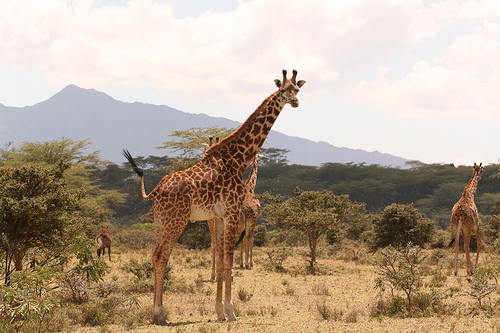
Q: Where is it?
A: This is at the plain.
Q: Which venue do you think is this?
A: This is a plain.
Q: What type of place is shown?
A: It is a plain.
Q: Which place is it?
A: It is a plain.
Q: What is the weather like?
A: It is overcast.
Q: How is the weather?
A: It is overcast.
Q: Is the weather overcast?
A: Yes, it is overcast.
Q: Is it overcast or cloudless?
A: It is overcast.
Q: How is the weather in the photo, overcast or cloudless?
A: It is overcast.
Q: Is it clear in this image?
A: No, it is overcast.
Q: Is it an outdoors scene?
A: Yes, it is outdoors.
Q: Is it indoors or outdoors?
A: It is outdoors.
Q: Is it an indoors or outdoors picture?
A: It is outdoors.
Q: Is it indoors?
A: No, it is outdoors.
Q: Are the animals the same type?
A: Yes, all the animals are giraffes.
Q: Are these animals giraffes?
A: Yes, all the animals are giraffes.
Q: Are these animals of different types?
A: No, all the animals are giraffes.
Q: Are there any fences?
A: No, there are no fences.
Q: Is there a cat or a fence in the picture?
A: No, there are no fences or cats.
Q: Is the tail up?
A: Yes, the tail is up.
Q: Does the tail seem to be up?
A: Yes, the tail is up.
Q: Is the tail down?
A: No, the tail is up.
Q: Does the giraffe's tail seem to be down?
A: No, the tail is up.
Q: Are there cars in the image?
A: No, there are no cars.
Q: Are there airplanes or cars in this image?
A: No, there are no cars or airplanes.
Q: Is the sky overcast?
A: Yes, the sky is overcast.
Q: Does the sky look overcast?
A: Yes, the sky is overcast.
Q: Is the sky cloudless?
A: No, the sky is overcast.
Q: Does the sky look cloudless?
A: No, the sky is overcast.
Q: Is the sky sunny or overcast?
A: The sky is overcast.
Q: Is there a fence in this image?
A: No, there are no fences.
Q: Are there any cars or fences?
A: No, there are no fences or cars.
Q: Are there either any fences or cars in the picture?
A: No, there are no fences or cars.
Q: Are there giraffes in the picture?
A: Yes, there is a giraffe.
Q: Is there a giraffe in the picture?
A: Yes, there is a giraffe.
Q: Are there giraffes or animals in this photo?
A: Yes, there is a giraffe.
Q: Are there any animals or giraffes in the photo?
A: Yes, there is a giraffe.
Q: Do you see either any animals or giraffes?
A: Yes, there is a giraffe.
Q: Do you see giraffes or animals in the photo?
A: Yes, there is a giraffe.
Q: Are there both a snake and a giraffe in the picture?
A: No, there is a giraffe but no snakes.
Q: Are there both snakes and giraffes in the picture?
A: No, there is a giraffe but no snakes.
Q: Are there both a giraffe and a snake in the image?
A: No, there is a giraffe but no snakes.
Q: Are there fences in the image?
A: No, there are no fences.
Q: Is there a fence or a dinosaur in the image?
A: No, there are no fences or dinosaurs.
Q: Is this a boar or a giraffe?
A: This is a giraffe.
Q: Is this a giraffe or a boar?
A: This is a giraffe.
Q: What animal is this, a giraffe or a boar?
A: This is a giraffe.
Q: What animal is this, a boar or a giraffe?
A: This is a giraffe.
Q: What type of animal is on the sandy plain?
A: The animal is a giraffe.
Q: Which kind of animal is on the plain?
A: The animal is a giraffe.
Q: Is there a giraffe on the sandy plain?
A: Yes, there is a giraffe on the plain.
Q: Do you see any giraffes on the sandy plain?
A: Yes, there is a giraffe on the plain.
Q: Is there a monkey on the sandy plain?
A: No, there is a giraffe on the plain.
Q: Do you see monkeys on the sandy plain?
A: No, there is a giraffe on the plain.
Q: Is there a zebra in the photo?
A: No, there are no zebras.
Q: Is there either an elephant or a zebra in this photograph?
A: No, there are no zebras or elephants.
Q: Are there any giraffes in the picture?
A: Yes, there is a giraffe.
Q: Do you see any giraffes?
A: Yes, there is a giraffe.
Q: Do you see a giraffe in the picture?
A: Yes, there is a giraffe.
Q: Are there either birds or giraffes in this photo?
A: Yes, there is a giraffe.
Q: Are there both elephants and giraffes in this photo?
A: No, there is a giraffe but no elephants.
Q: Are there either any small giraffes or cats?
A: Yes, there is a small giraffe.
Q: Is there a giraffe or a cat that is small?
A: Yes, the giraffe is small.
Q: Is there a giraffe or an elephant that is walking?
A: Yes, the giraffe is walking.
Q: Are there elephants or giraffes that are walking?
A: Yes, the giraffe is walking.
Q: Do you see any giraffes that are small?
A: Yes, there is a small giraffe.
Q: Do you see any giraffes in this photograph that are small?
A: Yes, there is a giraffe that is small.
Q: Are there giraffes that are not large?
A: Yes, there is a small giraffe.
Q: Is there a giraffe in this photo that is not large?
A: Yes, there is a small giraffe.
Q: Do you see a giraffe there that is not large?
A: Yes, there is a small giraffe.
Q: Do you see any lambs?
A: No, there are no lambs.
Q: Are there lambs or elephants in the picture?
A: No, there are no lambs or elephants.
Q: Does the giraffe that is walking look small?
A: Yes, the giraffe is small.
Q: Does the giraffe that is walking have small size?
A: Yes, the giraffe is small.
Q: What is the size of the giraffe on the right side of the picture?
A: The giraffe is small.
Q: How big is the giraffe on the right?
A: The giraffe is small.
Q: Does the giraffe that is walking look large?
A: No, the giraffe is small.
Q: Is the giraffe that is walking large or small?
A: The giraffe is small.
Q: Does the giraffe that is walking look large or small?
A: The giraffe is small.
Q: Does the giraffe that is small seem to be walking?
A: Yes, the giraffe is walking.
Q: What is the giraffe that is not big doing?
A: The giraffe is walking.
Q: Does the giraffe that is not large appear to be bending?
A: No, the giraffe is walking.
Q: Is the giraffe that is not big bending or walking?
A: The giraffe is walking.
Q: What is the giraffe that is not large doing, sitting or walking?
A: The giraffe is walking.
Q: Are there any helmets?
A: No, there are no helmets.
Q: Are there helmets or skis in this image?
A: No, there are no helmets or skis.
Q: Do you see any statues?
A: No, there are no statues.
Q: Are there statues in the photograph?
A: No, there are no statues.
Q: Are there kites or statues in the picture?
A: No, there are no statues or kites.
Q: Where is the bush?
A: The bush is on the plain.